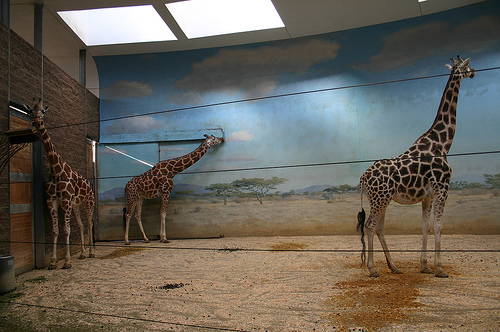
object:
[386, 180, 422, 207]
stomach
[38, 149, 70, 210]
chest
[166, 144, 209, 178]
neck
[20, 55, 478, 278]
giraffes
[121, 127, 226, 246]
giraffe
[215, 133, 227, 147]
nose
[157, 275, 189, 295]
poop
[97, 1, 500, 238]
backdrop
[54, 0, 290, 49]
lights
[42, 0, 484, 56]
ceiling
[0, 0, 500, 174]
enclosure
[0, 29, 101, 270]
wall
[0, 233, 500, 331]
dirt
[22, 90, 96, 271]
giraffe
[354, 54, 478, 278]
giraffe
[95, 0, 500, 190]
sky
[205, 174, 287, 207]
trees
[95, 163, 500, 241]
savannah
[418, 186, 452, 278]
legs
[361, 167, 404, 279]
legs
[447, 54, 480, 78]
horns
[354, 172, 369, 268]
tail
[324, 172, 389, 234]
turf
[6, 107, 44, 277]
door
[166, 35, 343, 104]
clouds